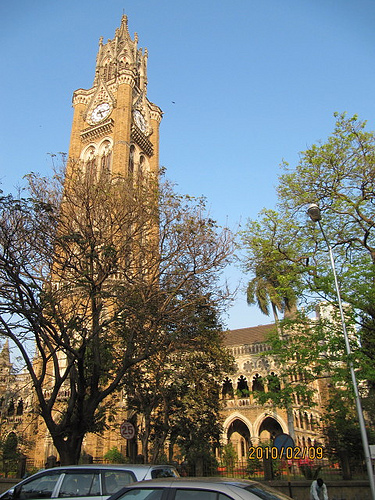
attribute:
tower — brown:
[71, 11, 155, 209]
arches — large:
[221, 411, 254, 469]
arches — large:
[252, 409, 297, 469]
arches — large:
[251, 369, 265, 394]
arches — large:
[265, 368, 283, 392]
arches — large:
[235, 373, 249, 396]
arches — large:
[219, 373, 235, 397]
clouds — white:
[165, 38, 335, 175]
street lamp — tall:
[306, 202, 375, 498]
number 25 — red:
[119, 424, 135, 435]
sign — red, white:
[112, 418, 138, 441]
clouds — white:
[6, 20, 54, 161]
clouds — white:
[195, 107, 225, 126]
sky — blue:
[1, 0, 354, 88]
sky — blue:
[4, 5, 374, 233]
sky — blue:
[1, 0, 370, 372]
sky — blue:
[171, 33, 295, 139]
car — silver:
[110, 473, 290, 499]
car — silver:
[0, 461, 178, 498]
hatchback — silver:
[0, 464, 180, 498]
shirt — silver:
[312, 479, 328, 498]